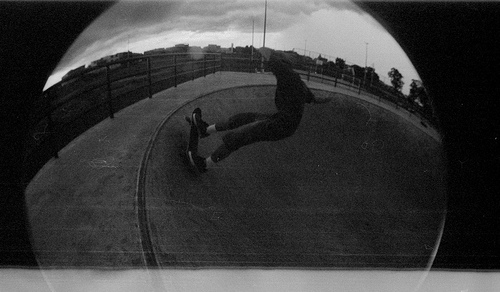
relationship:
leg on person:
[204, 107, 274, 134] [188, 47, 330, 170]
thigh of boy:
[236, 121, 269, 141] [188, 51, 336, 171]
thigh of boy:
[230, 108, 262, 123] [188, 51, 336, 171]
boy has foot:
[188, 51, 336, 171] [187, 149, 211, 178]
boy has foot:
[188, 51, 336, 171] [188, 103, 212, 142]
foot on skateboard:
[187, 149, 211, 178] [184, 101, 209, 181]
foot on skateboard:
[188, 103, 212, 142] [184, 101, 209, 181]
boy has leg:
[188, 51, 336, 171] [192, 107, 282, 135]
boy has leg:
[188, 51, 336, 171] [192, 121, 290, 176]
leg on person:
[175, 118, 295, 180] [186, 53, 340, 180]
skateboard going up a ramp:
[184, 101, 209, 181] [139, 81, 441, 265]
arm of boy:
[312, 85, 334, 107] [255, 54, 316, 161]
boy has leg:
[192, 51, 336, 171] [205, 106, 277, 132]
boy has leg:
[192, 51, 336, 171] [199, 121, 295, 165]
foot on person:
[188, 106, 210, 138] [188, 47, 330, 170]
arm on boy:
[262, 36, 269, 73] [211, 67, 306, 157]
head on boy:
[248, 40, 305, 83] [218, 51, 347, 164]